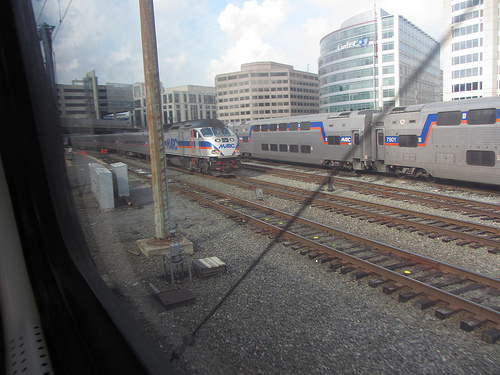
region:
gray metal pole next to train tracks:
[130, 0, 200, 262]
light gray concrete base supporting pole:
[135, 229, 197, 261]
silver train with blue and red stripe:
[63, 116, 248, 183]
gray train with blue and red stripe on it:
[183, 91, 498, 192]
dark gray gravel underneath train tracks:
[67, 148, 498, 374]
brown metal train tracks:
[68, 156, 498, 363]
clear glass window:
[8, 1, 498, 373]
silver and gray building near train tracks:
[308, 3, 448, 185]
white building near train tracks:
[436, 1, 498, 183]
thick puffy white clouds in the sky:
[161, 2, 474, 99]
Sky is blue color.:
[63, 16, 195, 74]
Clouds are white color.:
[231, 1, 322, 52]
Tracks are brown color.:
[266, 161, 436, 298]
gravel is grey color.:
[266, 286, 358, 365]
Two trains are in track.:
[164, 107, 413, 174]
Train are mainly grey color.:
[178, 109, 455, 181]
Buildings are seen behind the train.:
[108, 56, 458, 114]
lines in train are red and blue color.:
[164, 110, 434, 172]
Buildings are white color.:
[76, 17, 498, 106]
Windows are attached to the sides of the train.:
[240, 123, 491, 170]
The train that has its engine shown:
[75, 118, 245, 177]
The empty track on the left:
[95, 152, 498, 349]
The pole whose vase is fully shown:
[123, 1, 196, 258]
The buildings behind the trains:
[54, 0, 499, 128]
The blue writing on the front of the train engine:
[217, 141, 239, 153]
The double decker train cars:
[238, 91, 498, 191]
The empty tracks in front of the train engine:
[186, 171, 498, 344]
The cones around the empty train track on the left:
[74, 143, 111, 160]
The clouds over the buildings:
[28, 0, 443, 85]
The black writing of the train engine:
[208, 133, 238, 145]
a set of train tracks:
[100, 150, 497, 346]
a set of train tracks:
[223, 173, 498, 253]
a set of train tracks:
[242, 155, 498, 224]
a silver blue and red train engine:
[159, 121, 237, 177]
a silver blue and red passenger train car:
[250, 112, 362, 168]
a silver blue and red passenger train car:
[381, 100, 497, 188]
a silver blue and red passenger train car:
[118, 128, 155, 154]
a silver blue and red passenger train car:
[95, 129, 114, 151]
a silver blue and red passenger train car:
[67, 134, 88, 148]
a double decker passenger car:
[250, 115, 370, 172]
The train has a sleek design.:
[175, 110, 278, 230]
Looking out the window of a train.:
[32, 55, 177, 357]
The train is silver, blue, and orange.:
[254, 119, 379, 184]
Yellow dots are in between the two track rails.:
[256, 198, 424, 300]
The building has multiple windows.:
[220, 62, 298, 127]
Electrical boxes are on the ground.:
[82, 132, 139, 237]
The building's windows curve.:
[302, 20, 406, 120]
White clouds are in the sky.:
[202, 6, 311, 63]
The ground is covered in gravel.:
[248, 272, 410, 360]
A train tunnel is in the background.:
[64, 101, 129, 152]